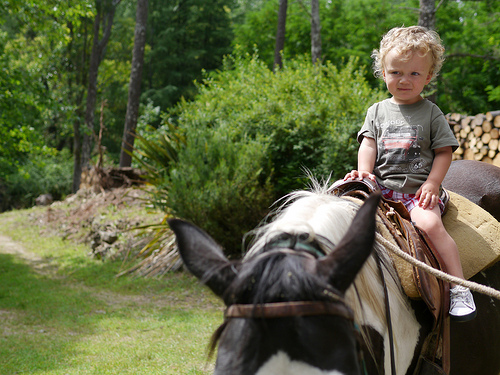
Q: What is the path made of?
A: Dirt.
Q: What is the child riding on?
A: A horse.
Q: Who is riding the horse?
A: A child.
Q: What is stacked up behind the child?
A: Wood logs.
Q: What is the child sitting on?
A: A saddle.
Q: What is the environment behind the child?
A: A forest.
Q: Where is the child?
A: On a horse.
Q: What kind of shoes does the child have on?
A: White.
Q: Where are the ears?
A: On the horse.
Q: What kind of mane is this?
A: White.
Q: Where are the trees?
A: In the back.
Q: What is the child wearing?
A: Shorts.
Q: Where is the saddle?
A: Under the child.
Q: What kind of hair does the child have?
A: Blonde.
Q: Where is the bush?
A: Behind the child.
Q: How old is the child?
A: Young.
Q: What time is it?
A: Afternoon.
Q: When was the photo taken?
A: During the daytime.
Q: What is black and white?
A: Animal.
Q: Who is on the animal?
A: A kid.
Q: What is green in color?
A: Grass.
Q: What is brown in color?
A: The saddle.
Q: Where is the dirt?
A: On grass.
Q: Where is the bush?
A: Behind the kid.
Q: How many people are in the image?
A: One.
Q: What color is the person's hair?
A: Blonde.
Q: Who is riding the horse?
A: The child.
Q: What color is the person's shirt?
A: Gray.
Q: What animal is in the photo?
A: Horse.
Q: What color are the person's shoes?
A: White.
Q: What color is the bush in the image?
A: Green.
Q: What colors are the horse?
A: Black and white.